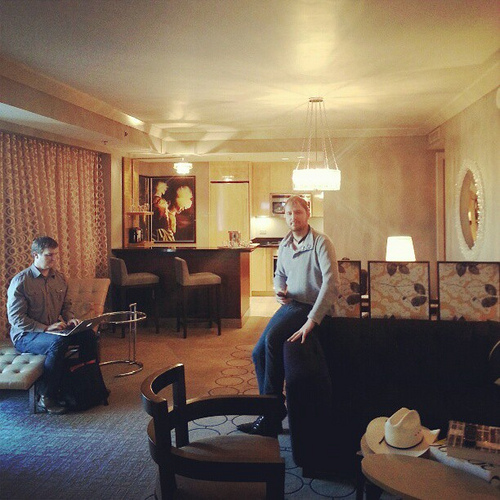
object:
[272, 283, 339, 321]
phone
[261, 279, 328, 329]
hand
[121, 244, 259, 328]
stool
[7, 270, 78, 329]
shirt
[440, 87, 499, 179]
wall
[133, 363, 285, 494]
chair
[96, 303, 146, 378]
table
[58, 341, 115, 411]
backpack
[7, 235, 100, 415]
man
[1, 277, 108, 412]
chair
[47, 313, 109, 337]
computer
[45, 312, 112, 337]
laptop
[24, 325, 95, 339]
lap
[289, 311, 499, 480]
couch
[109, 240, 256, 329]
bar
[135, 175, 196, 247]
picture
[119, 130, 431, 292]
wall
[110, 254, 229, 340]
chairs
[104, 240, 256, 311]
counter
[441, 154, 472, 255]
mirror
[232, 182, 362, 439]
man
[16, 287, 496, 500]
floor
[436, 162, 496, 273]
wall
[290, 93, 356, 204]
lights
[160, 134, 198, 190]
lights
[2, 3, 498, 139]
ceiling